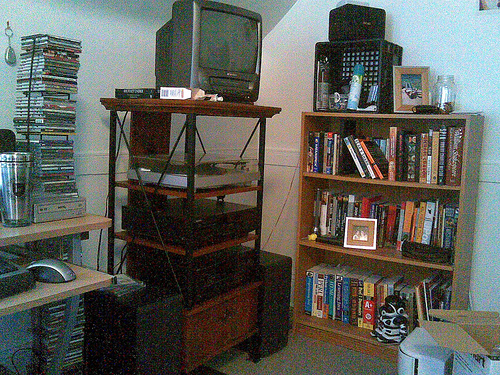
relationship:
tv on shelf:
[171, 11, 272, 102] [74, 46, 324, 355]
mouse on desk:
[22, 228, 83, 284] [3, 176, 193, 344]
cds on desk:
[7, 19, 108, 212] [3, 176, 193, 344]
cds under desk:
[7, 19, 108, 212] [3, 176, 193, 344]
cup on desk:
[2, 135, 40, 243] [3, 176, 193, 344]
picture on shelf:
[342, 211, 396, 257] [276, 188, 486, 263]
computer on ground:
[5, 269, 136, 373] [6, 293, 232, 361]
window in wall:
[460, 2, 498, 34] [421, 3, 500, 60]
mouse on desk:
[22, 228, 83, 284] [3, 212, 114, 368]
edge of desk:
[64, 199, 136, 264] [3, 176, 193, 344]